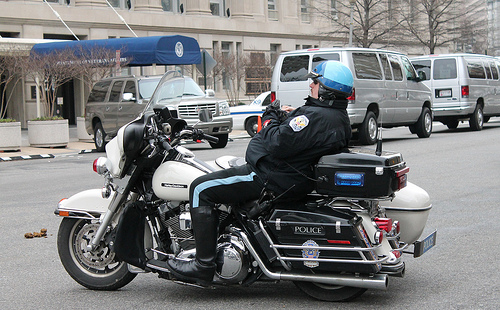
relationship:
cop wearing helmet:
[163, 60, 358, 289] [297, 53, 363, 97]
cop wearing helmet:
[163, 60, 358, 289] [311, 52, 354, 97]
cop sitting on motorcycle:
[163, 60, 358, 289] [41, 67, 422, 304]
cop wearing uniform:
[163, 60, 358, 289] [190, 99, 345, 276]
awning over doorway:
[23, 35, 217, 82] [46, 61, 82, 133]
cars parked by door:
[268, 47, 434, 145] [44, 71, 79, 128]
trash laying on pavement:
[26, 221, 54, 249] [2, 140, 79, 240]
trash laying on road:
[26, 221, 54, 249] [0, 118, 495, 308]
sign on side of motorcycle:
[296, 238, 320, 269] [71, 112, 450, 271]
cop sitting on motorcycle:
[182, 50, 394, 304] [31, 68, 461, 293]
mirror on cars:
[413, 69, 428, 81] [268, 47, 434, 145]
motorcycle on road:
[41, 67, 422, 304] [0, 118, 495, 308]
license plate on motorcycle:
[413, 229, 437, 258] [41, 67, 422, 304]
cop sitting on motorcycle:
[163, 60, 358, 289] [34, 105, 424, 307]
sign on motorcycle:
[288, 225, 327, 272] [55, 99, 440, 299]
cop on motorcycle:
[163, 60, 358, 289] [55, 99, 440, 299]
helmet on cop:
[297, 47, 375, 109] [163, 60, 358, 289]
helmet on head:
[297, 47, 375, 109] [304, 59, 354, 101]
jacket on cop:
[235, 104, 363, 175] [163, 60, 358, 289]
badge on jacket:
[288, 108, 309, 136] [244, 97, 350, 194]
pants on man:
[189, 163, 262, 206] [246, 52, 373, 223]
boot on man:
[159, 197, 220, 292] [154, 52, 357, 292]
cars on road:
[82, 73, 239, 150] [0, 118, 495, 308]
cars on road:
[221, 84, 279, 140] [0, 118, 495, 308]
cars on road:
[268, 42, 438, 144] [0, 118, 495, 308]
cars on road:
[410, 52, 499, 132] [0, 118, 495, 308]